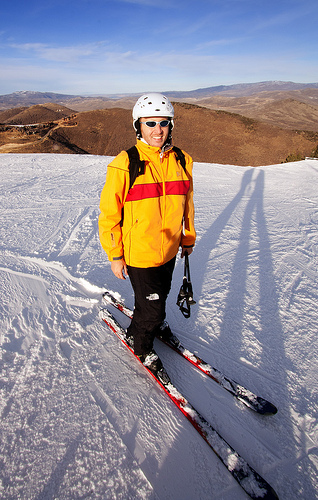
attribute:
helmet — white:
[130, 92, 175, 118]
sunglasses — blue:
[146, 118, 171, 128]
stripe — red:
[127, 180, 191, 203]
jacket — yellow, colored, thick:
[98, 138, 196, 269]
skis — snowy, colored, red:
[96, 292, 280, 500]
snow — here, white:
[0, 152, 316, 499]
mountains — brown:
[0, 0, 317, 166]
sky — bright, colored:
[2, 0, 318, 93]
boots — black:
[138, 320, 172, 371]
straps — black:
[127, 146, 187, 189]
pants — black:
[127, 256, 175, 354]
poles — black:
[177, 251, 197, 318]